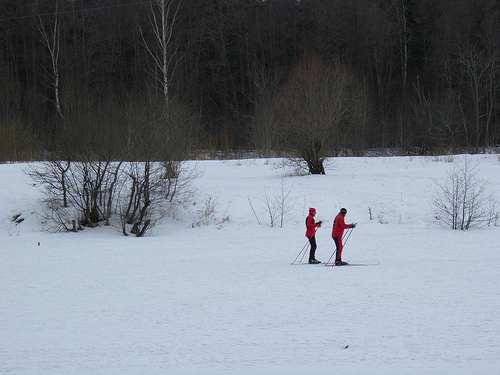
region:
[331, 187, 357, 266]
this is a man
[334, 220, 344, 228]
this is a jacket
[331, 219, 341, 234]
the jacket is red in color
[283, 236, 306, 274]
this is a stick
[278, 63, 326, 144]
this is a tree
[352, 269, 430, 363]
this is the snow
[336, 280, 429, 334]
the snow is white in color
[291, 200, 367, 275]
the men are two in number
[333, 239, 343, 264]
this is a trouser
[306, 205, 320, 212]
this is a cap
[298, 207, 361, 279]
two people using snowboard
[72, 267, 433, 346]
the place covered with full of snow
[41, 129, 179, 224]
trees with plants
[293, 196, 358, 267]
two persons wearing snowsuits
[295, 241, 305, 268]
people holding snowsticks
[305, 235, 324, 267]
a man wearing black color pant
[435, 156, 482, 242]
plant with snow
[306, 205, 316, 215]
a person wearing red color cap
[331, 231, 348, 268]
black color and red color pant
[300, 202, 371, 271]
two persons are standing in the snowboard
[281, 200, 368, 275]
two people skiing in snow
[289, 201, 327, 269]
person holding ski poles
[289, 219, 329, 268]
two ski poles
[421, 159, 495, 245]
short leafless tree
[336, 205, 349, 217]
black hat on person skiing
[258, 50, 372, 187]
brown leafless tree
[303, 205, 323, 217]
red hat on person skiing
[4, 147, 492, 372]
snow on ground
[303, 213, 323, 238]
person in red jacket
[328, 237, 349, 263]
black and red snow pants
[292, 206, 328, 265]
a cross country skier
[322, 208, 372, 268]
a cross country skier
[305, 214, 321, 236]
a red winter coat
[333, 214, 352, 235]
a red winter coat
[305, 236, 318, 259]
black snow pants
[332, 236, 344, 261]
red and black snow pants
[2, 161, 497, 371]
a white snowy field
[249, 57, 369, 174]
a large bare tree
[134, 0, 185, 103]
a large bare tree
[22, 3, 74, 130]
a large bare tree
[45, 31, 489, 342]
This picture is outside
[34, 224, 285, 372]
The ground is covered in snow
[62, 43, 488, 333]
it is cold here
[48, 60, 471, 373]
This is winter time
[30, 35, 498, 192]
The trees are dead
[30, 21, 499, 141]
The trees are bare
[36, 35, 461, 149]
The trees are brown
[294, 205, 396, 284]
These people are wearing red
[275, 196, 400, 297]
These people are skiing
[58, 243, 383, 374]
The snow on the ground is white